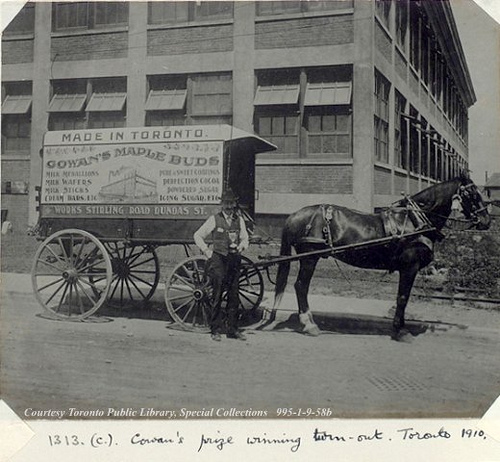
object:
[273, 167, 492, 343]
horse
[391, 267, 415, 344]
leg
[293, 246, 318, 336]
leg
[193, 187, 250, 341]
man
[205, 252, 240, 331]
pants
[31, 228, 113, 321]
wheel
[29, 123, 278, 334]
carriage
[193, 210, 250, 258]
shirt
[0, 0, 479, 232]
building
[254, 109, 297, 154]
window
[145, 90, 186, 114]
window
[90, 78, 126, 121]
window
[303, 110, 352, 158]
window